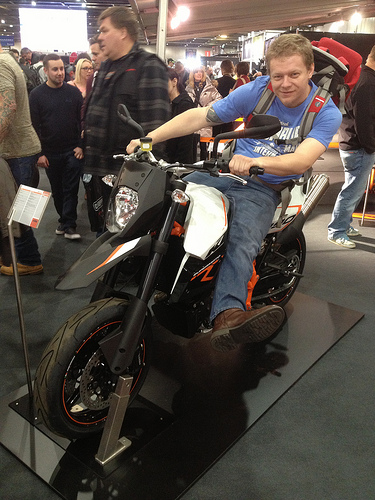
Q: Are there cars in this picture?
A: No, there are no cars.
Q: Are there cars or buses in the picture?
A: No, there are no cars or buses.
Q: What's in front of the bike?
A: The sign is in front of the bike.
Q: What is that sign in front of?
A: The sign is in front of the bike.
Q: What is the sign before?
A: The sign is in front of the bike.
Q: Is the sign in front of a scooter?
A: No, the sign is in front of the bike.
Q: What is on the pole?
A: The sign is on the pole.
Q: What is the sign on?
A: The sign is on the pole.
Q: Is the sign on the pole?
A: Yes, the sign is on the pole.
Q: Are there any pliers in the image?
A: No, there are no pliers.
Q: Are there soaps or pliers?
A: No, there are no pliers or soaps.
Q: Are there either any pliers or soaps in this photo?
A: No, there are no pliers or soaps.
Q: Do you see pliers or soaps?
A: No, there are no pliers or soaps.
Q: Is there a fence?
A: No, there are no fences.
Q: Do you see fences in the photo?
A: No, there are no fences.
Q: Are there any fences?
A: No, there are no fences.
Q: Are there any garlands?
A: No, there are no garlands.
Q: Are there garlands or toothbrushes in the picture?
A: No, there are no garlands or toothbrushes.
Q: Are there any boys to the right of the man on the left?
A: Yes, there is a boy to the right of the man.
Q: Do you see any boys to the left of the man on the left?
A: No, the boy is to the right of the man.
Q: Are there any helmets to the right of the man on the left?
A: No, there is a boy to the right of the man.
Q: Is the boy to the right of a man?
A: Yes, the boy is to the right of a man.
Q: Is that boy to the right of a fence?
A: No, the boy is to the right of a man.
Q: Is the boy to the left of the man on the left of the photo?
A: No, the boy is to the right of the man.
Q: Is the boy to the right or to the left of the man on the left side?
A: The boy is to the right of the man.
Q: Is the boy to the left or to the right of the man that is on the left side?
A: The boy is to the right of the man.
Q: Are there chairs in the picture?
A: No, there are no chairs.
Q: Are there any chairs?
A: No, there are no chairs.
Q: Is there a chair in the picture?
A: No, there are no chairs.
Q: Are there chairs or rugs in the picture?
A: No, there are no chairs or rugs.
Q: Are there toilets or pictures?
A: No, there are no pictures or toilets.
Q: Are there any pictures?
A: No, there are no pictures.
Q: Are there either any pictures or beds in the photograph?
A: No, there are no pictures or beds.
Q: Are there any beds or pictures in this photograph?
A: No, there are no pictures or beds.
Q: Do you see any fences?
A: No, there are no fences.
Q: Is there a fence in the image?
A: No, there are no fences.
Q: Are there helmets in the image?
A: No, there are no helmets.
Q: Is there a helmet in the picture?
A: No, there are no helmets.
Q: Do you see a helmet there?
A: No, there are no helmets.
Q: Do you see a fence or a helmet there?
A: No, there are no helmets or fences.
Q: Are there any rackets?
A: No, there are no rackets.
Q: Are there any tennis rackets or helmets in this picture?
A: No, there are no tennis rackets or helmets.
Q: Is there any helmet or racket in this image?
A: No, there are no rackets or helmets.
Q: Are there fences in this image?
A: No, there are no fences.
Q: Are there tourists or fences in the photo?
A: No, there are no fences or tourists.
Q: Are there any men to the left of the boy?
A: Yes, there is a man to the left of the boy.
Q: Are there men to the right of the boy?
A: No, the man is to the left of the boy.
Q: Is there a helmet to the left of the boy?
A: No, there is a man to the left of the boy.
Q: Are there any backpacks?
A: Yes, there is a backpack.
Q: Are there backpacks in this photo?
A: Yes, there is a backpack.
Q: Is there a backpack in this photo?
A: Yes, there is a backpack.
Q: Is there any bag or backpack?
A: Yes, there is a backpack.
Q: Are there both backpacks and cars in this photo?
A: No, there is a backpack but no cars.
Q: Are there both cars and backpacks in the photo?
A: No, there is a backpack but no cars.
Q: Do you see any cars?
A: No, there are no cars.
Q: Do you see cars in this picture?
A: No, there are no cars.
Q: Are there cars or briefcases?
A: No, there are no cars or briefcases.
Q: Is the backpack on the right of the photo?
A: Yes, the backpack is on the right of the image.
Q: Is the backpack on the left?
A: No, the backpack is on the right of the image.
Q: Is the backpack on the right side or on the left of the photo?
A: The backpack is on the right of the image.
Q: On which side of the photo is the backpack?
A: The backpack is on the right of the image.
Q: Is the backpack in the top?
A: Yes, the backpack is in the top of the image.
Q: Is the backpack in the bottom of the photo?
A: No, the backpack is in the top of the image.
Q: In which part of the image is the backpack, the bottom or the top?
A: The backpack is in the top of the image.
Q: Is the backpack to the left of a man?
A: No, the backpack is to the right of a man.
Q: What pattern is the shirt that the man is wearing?
A: The shirt is striped.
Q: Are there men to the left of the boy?
A: Yes, there is a man to the left of the boy.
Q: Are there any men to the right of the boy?
A: No, the man is to the left of the boy.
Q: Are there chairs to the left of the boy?
A: No, there is a man to the left of the boy.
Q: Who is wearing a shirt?
A: The man is wearing a shirt.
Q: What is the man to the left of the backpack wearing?
A: The man is wearing a shirt.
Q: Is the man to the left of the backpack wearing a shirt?
A: Yes, the man is wearing a shirt.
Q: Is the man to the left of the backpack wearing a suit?
A: No, the man is wearing a shirt.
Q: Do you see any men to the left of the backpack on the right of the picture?
A: Yes, there is a man to the left of the backpack.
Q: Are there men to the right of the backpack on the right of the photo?
A: No, the man is to the left of the backpack.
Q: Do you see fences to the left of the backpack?
A: No, there is a man to the left of the backpack.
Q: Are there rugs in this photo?
A: No, there are no rugs.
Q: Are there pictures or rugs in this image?
A: No, there are no rugs or pictures.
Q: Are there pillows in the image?
A: No, there are no pillows.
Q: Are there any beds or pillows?
A: No, there are no pillows or beds.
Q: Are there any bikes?
A: Yes, there is a bike.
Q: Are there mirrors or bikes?
A: Yes, there is a bike.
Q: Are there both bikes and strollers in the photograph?
A: No, there is a bike but no strollers.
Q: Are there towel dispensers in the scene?
A: No, there are no towel dispensers.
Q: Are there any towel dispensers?
A: No, there are no towel dispensers.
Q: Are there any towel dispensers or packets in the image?
A: No, there are no towel dispensers or packets.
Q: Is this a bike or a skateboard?
A: This is a bike.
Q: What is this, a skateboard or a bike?
A: This is a bike.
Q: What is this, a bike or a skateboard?
A: This is a bike.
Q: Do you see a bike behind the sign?
A: Yes, there is a bike behind the sign.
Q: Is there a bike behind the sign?
A: Yes, there is a bike behind the sign.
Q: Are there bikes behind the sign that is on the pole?
A: Yes, there is a bike behind the sign.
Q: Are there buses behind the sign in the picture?
A: No, there is a bike behind the sign.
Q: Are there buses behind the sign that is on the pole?
A: No, there is a bike behind the sign.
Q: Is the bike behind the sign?
A: Yes, the bike is behind the sign.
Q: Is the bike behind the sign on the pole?
A: Yes, the bike is behind the sign.